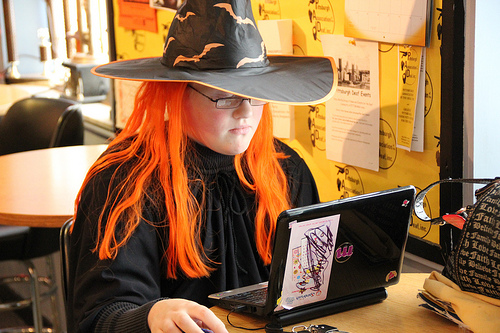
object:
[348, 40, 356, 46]
pin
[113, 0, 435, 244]
bullentin board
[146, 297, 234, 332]
hand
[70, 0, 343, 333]
kid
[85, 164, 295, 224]
cape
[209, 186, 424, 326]
laptop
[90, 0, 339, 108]
hat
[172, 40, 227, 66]
bat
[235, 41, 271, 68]
bat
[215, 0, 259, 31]
bat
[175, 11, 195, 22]
bat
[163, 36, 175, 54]
bat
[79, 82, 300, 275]
hair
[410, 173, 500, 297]
purse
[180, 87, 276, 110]
eyeglasses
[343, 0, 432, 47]
paper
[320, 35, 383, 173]
paper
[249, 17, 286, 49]
paper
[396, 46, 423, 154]
paper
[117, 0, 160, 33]
paper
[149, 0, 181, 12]
paper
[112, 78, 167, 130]
paper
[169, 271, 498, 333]
table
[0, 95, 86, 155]
chair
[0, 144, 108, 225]
table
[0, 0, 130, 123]
window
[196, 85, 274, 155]
face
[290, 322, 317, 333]
keys